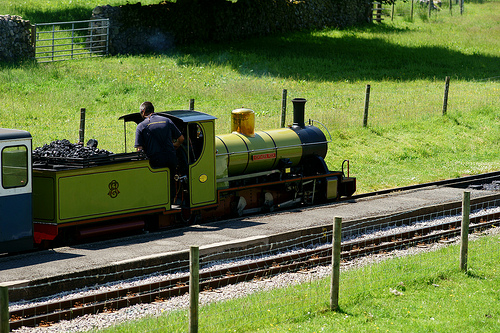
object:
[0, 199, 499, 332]
fence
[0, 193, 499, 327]
train tracks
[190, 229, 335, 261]
wire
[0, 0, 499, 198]
grass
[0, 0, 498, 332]
ground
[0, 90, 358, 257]
train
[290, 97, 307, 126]
smoke stack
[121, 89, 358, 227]
engine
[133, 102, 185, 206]
man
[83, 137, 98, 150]
coal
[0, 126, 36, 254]
car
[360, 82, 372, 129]
post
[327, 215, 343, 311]
post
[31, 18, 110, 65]
gate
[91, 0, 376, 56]
stone wall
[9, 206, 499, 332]
gravel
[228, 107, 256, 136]
boiler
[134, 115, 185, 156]
shirt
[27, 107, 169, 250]
car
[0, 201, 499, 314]
barbed wire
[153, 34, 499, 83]
shadow